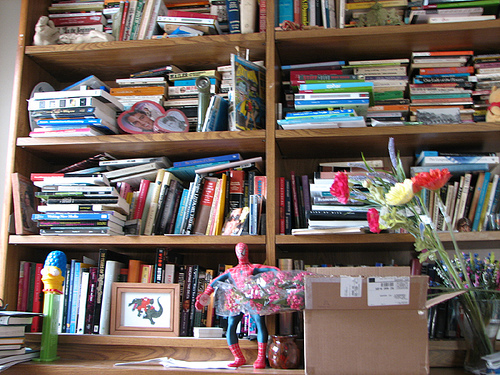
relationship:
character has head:
[40, 251, 65, 360] [40, 251, 66, 293]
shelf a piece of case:
[275, 123, 496, 139] [273, 3, 496, 372]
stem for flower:
[404, 204, 489, 347] [385, 178, 416, 206]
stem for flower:
[404, 204, 487, 347] [411, 167, 451, 191]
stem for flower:
[404, 204, 487, 347] [329, 170, 350, 204]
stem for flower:
[404, 204, 487, 347] [367, 207, 380, 232]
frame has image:
[155, 106, 190, 134] [162, 118, 185, 128]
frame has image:
[117, 101, 165, 133] [128, 110, 154, 129]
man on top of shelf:
[195, 243, 284, 369] [13, 356, 303, 372]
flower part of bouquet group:
[411, 167, 451, 191] [329, 137, 494, 355]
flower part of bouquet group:
[385, 178, 416, 206] [329, 137, 494, 355]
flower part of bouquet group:
[367, 207, 380, 232] [329, 137, 494, 355]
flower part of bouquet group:
[329, 170, 350, 204] [329, 137, 494, 355]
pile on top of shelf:
[4, 311, 38, 370] [13, 356, 303, 372]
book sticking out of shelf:
[233, 53, 265, 130] [17, 131, 268, 145]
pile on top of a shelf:
[4, 311, 38, 370] [13, 356, 303, 372]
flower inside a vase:
[411, 167, 451, 191] [447, 298, 497, 372]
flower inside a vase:
[385, 178, 416, 206] [447, 298, 497, 372]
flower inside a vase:
[367, 207, 380, 232] [447, 298, 497, 372]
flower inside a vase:
[329, 170, 350, 204] [447, 298, 497, 372]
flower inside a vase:
[387, 136, 403, 182] [447, 298, 497, 372]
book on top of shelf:
[134, 180, 150, 220] [6, 141, 269, 243]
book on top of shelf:
[171, 155, 241, 168] [6, 141, 269, 243]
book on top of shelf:
[31, 213, 130, 224] [6, 141, 269, 243]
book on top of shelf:
[193, 176, 217, 237] [6, 141, 269, 243]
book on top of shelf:
[249, 193, 259, 234] [6, 141, 269, 243]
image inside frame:
[162, 118, 185, 128] [155, 106, 190, 134]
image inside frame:
[128, 110, 154, 129] [117, 101, 165, 133]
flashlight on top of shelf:
[196, 75, 210, 133] [17, 131, 268, 145]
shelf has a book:
[6, 141, 269, 243] [31, 213, 130, 224]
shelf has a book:
[6, 141, 269, 243] [134, 180, 150, 220]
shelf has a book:
[6, 141, 269, 243] [171, 155, 241, 168]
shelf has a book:
[6, 141, 269, 243] [193, 176, 217, 237]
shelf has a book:
[6, 141, 269, 243] [249, 193, 259, 234]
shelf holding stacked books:
[275, 123, 496, 139] [279, 48, 497, 128]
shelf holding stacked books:
[17, 131, 268, 145] [25, 43, 266, 132]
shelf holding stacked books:
[6, 141, 269, 243] [12, 151, 266, 234]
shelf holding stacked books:
[27, 32, 268, 54] [31, 4, 265, 47]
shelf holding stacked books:
[277, 233, 498, 242] [275, 139, 494, 234]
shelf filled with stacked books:
[275, 123, 496, 139] [279, 48, 497, 128]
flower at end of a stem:
[411, 167, 451, 191] [404, 204, 487, 347]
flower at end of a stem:
[367, 207, 380, 232] [404, 204, 487, 347]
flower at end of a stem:
[329, 170, 350, 204] [404, 204, 487, 347]